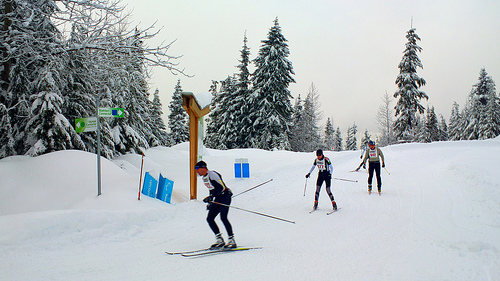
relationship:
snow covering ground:
[0, 147, 484, 206] [6, 215, 499, 277]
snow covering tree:
[0, 0, 500, 158] [0, 2, 90, 155]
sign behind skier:
[98, 106, 126, 118] [194, 159, 238, 247]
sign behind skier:
[75, 116, 100, 132] [194, 159, 238, 247]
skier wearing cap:
[194, 159, 238, 247] [194, 160, 208, 169]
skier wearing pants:
[194, 159, 238, 247] [205, 194, 235, 240]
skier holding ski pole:
[194, 159, 238, 247] [209, 198, 298, 224]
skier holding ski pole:
[194, 159, 238, 247] [227, 178, 275, 199]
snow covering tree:
[0, 0, 500, 158] [252, 16, 293, 151]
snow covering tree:
[398, 73, 412, 80] [395, 17, 427, 141]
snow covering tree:
[0, 0, 500, 158] [470, 67, 496, 142]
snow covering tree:
[0, 0, 500, 158] [123, 24, 153, 148]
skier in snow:
[194, 159, 238, 247] [0, 138, 500, 281]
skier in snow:
[311, 157, 338, 210] [0, 138, 500, 281]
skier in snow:
[363, 141, 386, 192] [0, 138, 500, 281]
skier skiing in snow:
[194, 159, 238, 247] [0, 138, 500, 281]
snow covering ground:
[0, 138, 500, 281] [6, 215, 499, 277]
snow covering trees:
[0, 0, 500, 158] [1, 2, 168, 152]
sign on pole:
[98, 106, 126, 118] [95, 96, 102, 195]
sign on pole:
[75, 116, 100, 132] [95, 96, 102, 195]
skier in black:
[194, 159, 238, 247] [205, 194, 235, 240]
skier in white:
[194, 159, 238, 247] [201, 172, 223, 194]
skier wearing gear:
[194, 159, 238, 247] [194, 160, 208, 169]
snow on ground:
[0, 138, 500, 281] [6, 215, 499, 277]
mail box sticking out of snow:
[183, 89, 214, 199] [0, 138, 500, 281]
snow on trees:
[0, 0, 500, 158] [1, 2, 168, 152]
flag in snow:
[156, 174, 174, 202] [0, 145, 175, 210]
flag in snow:
[142, 173, 159, 199] [0, 145, 175, 210]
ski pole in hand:
[209, 198, 298, 224] [204, 194, 216, 207]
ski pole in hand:
[227, 178, 275, 199] [204, 194, 216, 207]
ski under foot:
[326, 199, 344, 218] [330, 199, 340, 211]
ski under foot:
[310, 208, 321, 215] [312, 198, 319, 207]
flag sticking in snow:
[156, 174, 174, 202] [0, 145, 175, 210]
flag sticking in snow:
[142, 173, 159, 199] [0, 145, 175, 210]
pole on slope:
[95, 96, 102, 195] [0, 145, 175, 210]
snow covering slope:
[0, 147, 484, 206] [30, 147, 472, 266]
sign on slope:
[98, 106, 126, 118] [30, 147, 472, 266]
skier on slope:
[194, 159, 238, 247] [30, 147, 472, 266]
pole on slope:
[95, 96, 102, 195] [30, 147, 472, 266]